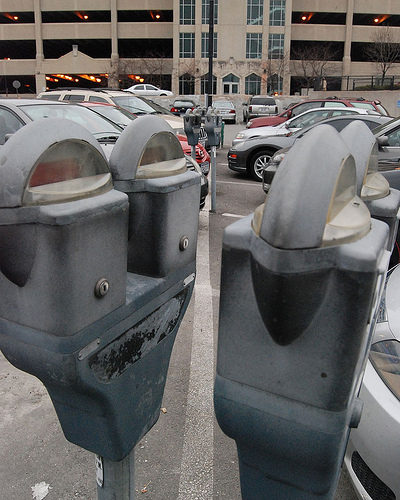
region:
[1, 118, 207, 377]
Two traffic meters are on the pole.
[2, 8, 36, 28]
The lights are turned on in the parking lot.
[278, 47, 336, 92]
The trees don't have any leaves.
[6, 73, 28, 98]
The stop sign is facing the parking lot.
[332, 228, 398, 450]
The meter is next to the white car.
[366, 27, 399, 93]
The tree is next to the fence.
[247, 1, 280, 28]
The staircase is seen in the window.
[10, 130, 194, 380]
a double parking meter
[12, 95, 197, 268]
cars parked in a lot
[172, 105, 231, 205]
vehicles parked by parking meters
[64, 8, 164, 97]
a parking garage with three levels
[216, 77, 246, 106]
a set of glass doors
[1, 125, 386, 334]
two sets of parking meters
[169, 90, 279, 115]
three cars parked next to a wall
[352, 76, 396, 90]
a metal railing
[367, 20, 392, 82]
a tree with no leaves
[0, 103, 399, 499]
Parking meters in a parking lot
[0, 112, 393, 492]
Parking meters in a parking lot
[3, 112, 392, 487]
Parking meters in a parking lot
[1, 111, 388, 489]
Parking meters in a parking lot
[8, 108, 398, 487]
Parking meters in a parking lot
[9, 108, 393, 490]
Parking meters in a parking lot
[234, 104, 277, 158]
An assortment of vehicles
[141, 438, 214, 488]
Grey colored littered tarmac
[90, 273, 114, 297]
Silver colored key hole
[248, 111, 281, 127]
Small packed maroon car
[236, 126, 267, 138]
White car between two cars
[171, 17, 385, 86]
White colored large apartment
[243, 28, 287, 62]
Large sized building windows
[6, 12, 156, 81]
Large lit white building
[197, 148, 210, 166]
Front of red car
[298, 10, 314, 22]
Orange colored illuminating lamps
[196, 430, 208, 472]
part of a wall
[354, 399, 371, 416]
edge of a car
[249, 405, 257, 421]
part of a pole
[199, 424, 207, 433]
side of a car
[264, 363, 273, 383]
edge of a pole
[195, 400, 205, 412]
edge of a road